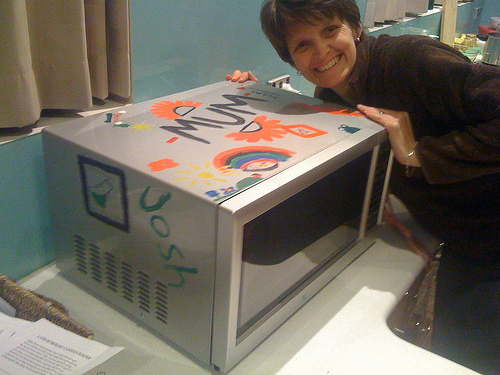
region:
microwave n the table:
[99, 77, 466, 352]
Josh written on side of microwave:
[130, 168, 256, 318]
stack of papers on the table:
[13, 317, 135, 373]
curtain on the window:
[9, 4, 160, 131]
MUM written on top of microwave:
[158, 86, 267, 147]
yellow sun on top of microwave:
[167, 155, 251, 215]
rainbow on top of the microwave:
[198, 144, 319, 164]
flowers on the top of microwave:
[137, 154, 267, 216]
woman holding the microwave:
[211, 13, 414, 175]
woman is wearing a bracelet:
[395, 123, 479, 177]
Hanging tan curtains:
[5, 3, 112, 110]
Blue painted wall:
[142, 11, 240, 67]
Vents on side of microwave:
[70, 226, 135, 297]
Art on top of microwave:
[155, 98, 279, 183]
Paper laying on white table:
[13, 311, 97, 368]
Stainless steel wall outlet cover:
[264, 75, 296, 91]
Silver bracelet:
[392, 141, 430, 188]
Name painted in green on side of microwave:
[135, 178, 199, 300]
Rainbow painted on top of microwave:
[215, 140, 299, 179]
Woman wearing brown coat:
[263, 4, 477, 132]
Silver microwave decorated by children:
[156, 96, 381, 338]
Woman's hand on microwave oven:
[333, 68, 418, 148]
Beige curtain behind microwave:
[5, 8, 131, 108]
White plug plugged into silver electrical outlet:
[270, 73, 299, 100]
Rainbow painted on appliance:
[210, 143, 286, 177]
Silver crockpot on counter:
[478, 32, 499, 72]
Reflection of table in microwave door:
[250, 226, 370, 321]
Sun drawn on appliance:
[177, 158, 234, 195]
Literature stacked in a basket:
[7, 286, 94, 370]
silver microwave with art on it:
[34, 75, 400, 371]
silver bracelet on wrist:
[398, 132, 421, 191]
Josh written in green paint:
[135, 176, 200, 311]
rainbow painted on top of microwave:
[205, 142, 296, 177]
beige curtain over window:
[3, 3, 140, 135]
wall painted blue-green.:
[147, 6, 267, 71]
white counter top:
[268, 247, 425, 364]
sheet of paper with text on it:
[5, 309, 120, 374]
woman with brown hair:
[262, 2, 379, 99]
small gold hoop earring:
[293, 65, 309, 81]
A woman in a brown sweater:
[263, 0, 499, 237]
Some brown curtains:
[0, 0, 132, 134]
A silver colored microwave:
[43, 75, 387, 369]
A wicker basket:
[1, 278, 93, 338]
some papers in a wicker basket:
[3, 304, 123, 372]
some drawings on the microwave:
[106, 80, 362, 195]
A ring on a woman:
[378, 105, 385, 117]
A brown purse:
[387, 206, 499, 369]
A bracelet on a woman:
[400, 145, 422, 181]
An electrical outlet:
[264, 75, 290, 88]